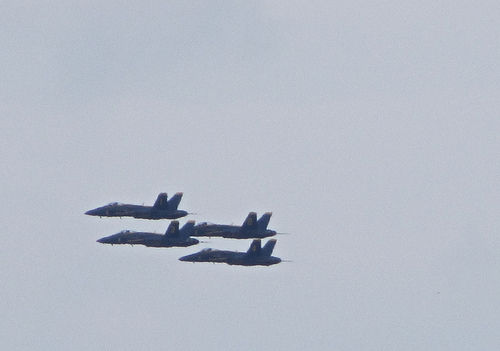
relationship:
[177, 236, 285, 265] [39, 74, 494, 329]
planes in sky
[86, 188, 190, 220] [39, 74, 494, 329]
airplanes in sky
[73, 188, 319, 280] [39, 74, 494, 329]
airplanes in sky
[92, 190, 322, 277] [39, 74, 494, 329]
planes in sky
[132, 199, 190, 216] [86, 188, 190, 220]
wings on airplanes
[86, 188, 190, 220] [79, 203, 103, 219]
airplanes has nose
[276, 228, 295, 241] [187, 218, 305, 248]
steam back of plane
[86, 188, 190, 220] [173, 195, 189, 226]
airplanes has end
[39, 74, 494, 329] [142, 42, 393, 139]
sky has clouds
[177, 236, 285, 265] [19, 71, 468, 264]
planes in air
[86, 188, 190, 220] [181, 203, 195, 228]
airplanes has back